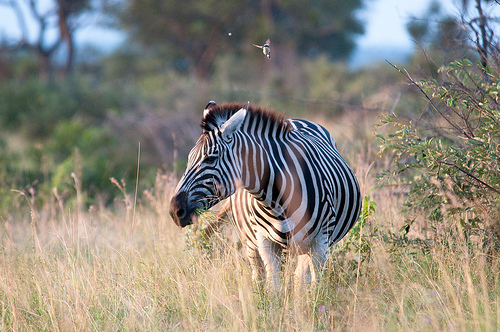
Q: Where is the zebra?
A: In a field.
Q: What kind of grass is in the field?
A: Tall grass.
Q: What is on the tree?
A: Green leaves.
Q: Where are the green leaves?
A: On the tree.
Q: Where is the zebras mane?
A: On the zebra's back.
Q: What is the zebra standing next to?
A: A tree.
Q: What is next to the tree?
A: Zebra.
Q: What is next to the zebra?
A: Tree.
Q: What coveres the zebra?
A: Stripes.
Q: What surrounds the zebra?
A: Tall grass.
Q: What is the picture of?
A: Head of a zebra.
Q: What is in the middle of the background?
A: A tree.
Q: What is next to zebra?
A: A bush.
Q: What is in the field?
A: Tall grass.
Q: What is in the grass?
A: Zebra.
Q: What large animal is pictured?
A: Zebra.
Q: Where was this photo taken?
A: Africa.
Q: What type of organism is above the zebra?
A: An insect.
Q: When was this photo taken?
A: Day time.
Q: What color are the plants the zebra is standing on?
A: Wheat yellow.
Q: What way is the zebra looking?
A: Right.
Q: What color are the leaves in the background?
A: Green.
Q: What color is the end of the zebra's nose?
A: Black.